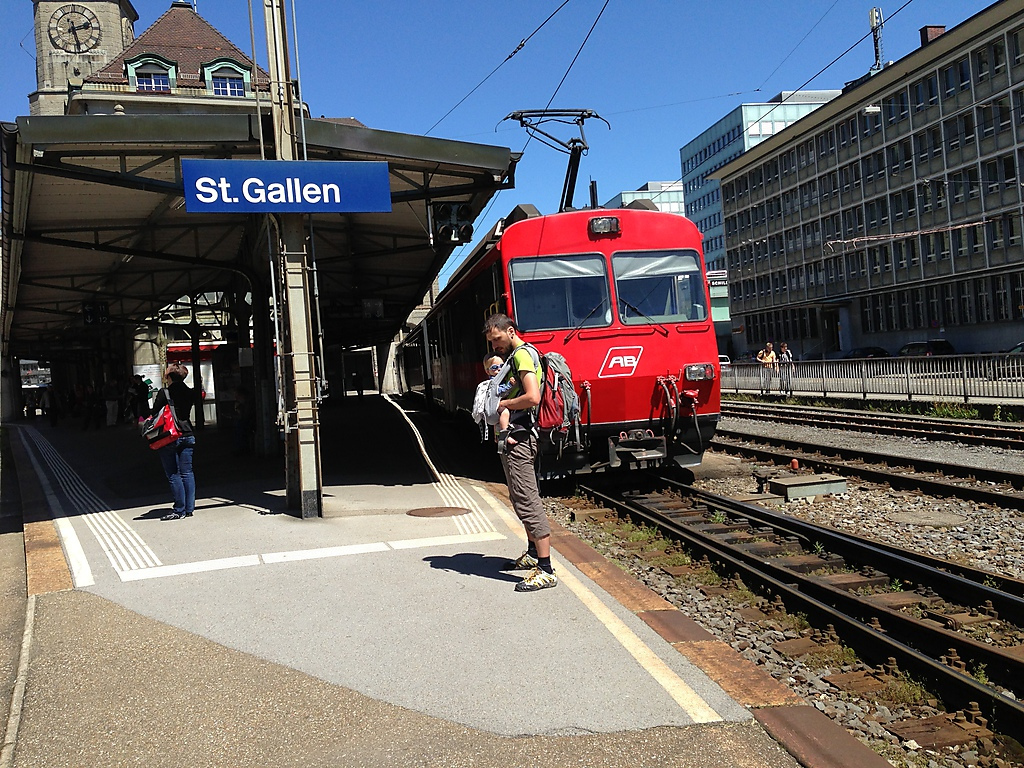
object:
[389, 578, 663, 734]
platform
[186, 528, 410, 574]
lines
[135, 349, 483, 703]
platform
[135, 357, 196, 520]
woman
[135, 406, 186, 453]
bag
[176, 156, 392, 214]
sign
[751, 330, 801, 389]
people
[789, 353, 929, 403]
fence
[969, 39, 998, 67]
window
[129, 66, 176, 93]
window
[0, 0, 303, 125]
building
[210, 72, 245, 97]
window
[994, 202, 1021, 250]
window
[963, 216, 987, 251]
window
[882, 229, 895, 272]
window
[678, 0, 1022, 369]
building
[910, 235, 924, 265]
window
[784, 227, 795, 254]
window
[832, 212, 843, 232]
window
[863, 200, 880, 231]
window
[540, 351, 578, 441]
backpack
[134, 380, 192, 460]
woman's handbag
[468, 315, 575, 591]
man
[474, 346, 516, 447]
toddler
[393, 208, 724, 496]
train